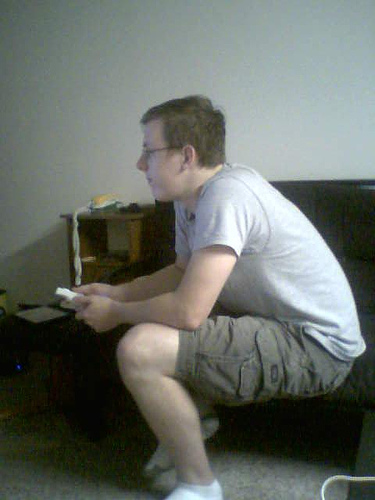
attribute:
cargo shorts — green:
[172, 313, 356, 404]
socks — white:
[139, 407, 229, 498]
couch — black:
[73, 183, 374, 495]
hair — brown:
[139, 93, 230, 170]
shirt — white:
[163, 161, 372, 360]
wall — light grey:
[2, 6, 372, 304]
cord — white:
[322, 474, 354, 481]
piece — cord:
[327, 465, 372, 480]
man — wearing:
[185, 259, 336, 348]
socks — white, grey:
[178, 479, 216, 500]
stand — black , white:
[22, 296, 52, 343]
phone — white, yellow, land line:
[80, 184, 112, 202]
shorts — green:
[209, 332, 288, 358]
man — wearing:
[170, 162, 240, 250]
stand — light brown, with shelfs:
[85, 203, 138, 245]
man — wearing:
[164, 197, 291, 280]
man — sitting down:
[163, 128, 302, 262]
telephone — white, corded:
[76, 186, 103, 228]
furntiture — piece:
[99, 215, 139, 240]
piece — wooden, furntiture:
[76, 215, 144, 229]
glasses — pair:
[148, 150, 159, 151]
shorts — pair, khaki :
[193, 339, 336, 369]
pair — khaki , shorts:
[218, 365, 278, 386]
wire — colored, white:
[307, 486, 356, 500]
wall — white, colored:
[52, 40, 222, 65]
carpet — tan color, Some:
[28, 444, 38, 477]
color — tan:
[56, 454, 120, 472]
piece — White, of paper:
[26, 298, 40, 319]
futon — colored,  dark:
[335, 186, 354, 228]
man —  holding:
[209, 214, 245, 239]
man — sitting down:
[163, 125, 252, 262]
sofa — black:
[293, 197, 348, 203]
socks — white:
[182, 488, 201, 493]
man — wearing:
[176, 150, 189, 182]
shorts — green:
[213, 341, 253, 380]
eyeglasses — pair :
[144, 150, 178, 158]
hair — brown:
[181, 108, 198, 140]